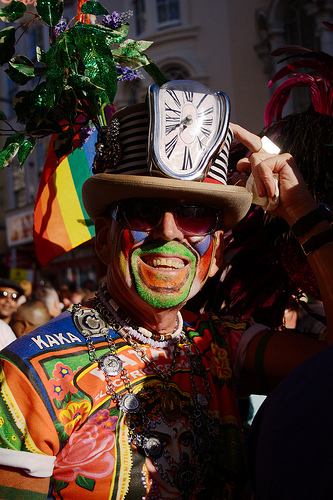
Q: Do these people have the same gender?
A: No, they are both male and female.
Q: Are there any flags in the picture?
A: Yes, there is a flag.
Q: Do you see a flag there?
A: Yes, there is a flag.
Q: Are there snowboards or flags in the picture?
A: Yes, there is a flag.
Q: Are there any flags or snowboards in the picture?
A: Yes, there is a flag.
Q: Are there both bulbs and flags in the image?
A: No, there is a flag but no light bulbs.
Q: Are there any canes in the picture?
A: No, there are no canes.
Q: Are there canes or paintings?
A: No, there are no canes or paintings.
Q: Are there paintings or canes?
A: No, there are no canes or paintings.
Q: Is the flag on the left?
A: Yes, the flag is on the left of the image.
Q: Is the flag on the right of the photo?
A: No, the flag is on the left of the image.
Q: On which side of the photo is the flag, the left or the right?
A: The flag is on the left of the image.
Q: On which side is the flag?
A: The flag is on the left of the image.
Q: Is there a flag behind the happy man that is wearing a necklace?
A: Yes, there is a flag behind the man.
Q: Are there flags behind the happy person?
A: Yes, there is a flag behind the man.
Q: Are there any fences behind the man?
A: No, there is a flag behind the man.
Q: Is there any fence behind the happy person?
A: No, there is a flag behind the man.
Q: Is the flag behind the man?
A: Yes, the flag is behind the man.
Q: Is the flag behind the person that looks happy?
A: Yes, the flag is behind the man.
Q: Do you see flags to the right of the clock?
A: No, the flag is to the left of the clock.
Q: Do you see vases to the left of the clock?
A: No, there is a flag to the left of the clock.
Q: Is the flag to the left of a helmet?
A: No, the flag is to the left of the clock.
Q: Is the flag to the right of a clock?
A: No, the flag is to the left of a clock.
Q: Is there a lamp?
A: No, there are no lamps.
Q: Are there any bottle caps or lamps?
A: No, there are no lamps or bottle caps.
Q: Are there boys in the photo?
A: No, there are no boys.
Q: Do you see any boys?
A: No, there are no boys.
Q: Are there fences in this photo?
A: No, there are no fences.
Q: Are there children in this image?
A: No, there are no children.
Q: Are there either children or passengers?
A: No, there are no children or passengers.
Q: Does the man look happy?
A: Yes, the man is happy.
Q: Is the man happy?
A: Yes, the man is happy.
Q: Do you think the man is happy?
A: Yes, the man is happy.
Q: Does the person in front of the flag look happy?
A: Yes, the man is happy.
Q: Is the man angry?
A: No, the man is happy.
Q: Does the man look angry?
A: No, the man is happy.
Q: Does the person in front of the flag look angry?
A: No, the man is happy.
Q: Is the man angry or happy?
A: The man is happy.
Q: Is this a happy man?
A: Yes, this is a happy man.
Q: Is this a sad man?
A: No, this is a happy man.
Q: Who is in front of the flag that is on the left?
A: The man is in front of the flag.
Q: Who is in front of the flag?
A: The man is in front of the flag.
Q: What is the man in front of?
A: The man is in front of the flag.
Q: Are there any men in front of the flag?
A: Yes, there is a man in front of the flag.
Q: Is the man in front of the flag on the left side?
A: Yes, the man is in front of the flag.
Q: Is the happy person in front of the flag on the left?
A: Yes, the man is in front of the flag.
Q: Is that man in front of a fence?
A: No, the man is in front of the flag.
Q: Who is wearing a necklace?
A: The man is wearing a necklace.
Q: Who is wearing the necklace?
A: The man is wearing a necklace.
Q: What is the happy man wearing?
A: The man is wearing a necklace.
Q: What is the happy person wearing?
A: The man is wearing a necklace.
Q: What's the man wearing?
A: The man is wearing a necklace.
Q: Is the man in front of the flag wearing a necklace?
A: Yes, the man is wearing a necklace.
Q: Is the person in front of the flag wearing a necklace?
A: Yes, the man is wearing a necklace.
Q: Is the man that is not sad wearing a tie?
A: No, the man is wearing a necklace.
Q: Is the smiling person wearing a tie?
A: No, the man is wearing a necklace.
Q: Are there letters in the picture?
A: Yes, there are letters.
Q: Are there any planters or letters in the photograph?
A: Yes, there are letters.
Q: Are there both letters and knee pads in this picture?
A: No, there are letters but no knee pads.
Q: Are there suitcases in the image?
A: No, there are no suitcases.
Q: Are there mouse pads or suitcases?
A: No, there are no suitcases or mouse pads.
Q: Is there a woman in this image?
A: Yes, there is a woman.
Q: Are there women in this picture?
A: Yes, there is a woman.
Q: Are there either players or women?
A: Yes, there is a woman.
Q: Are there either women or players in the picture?
A: Yes, there is a woman.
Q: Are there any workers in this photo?
A: No, there are no workers.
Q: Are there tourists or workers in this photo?
A: No, there are no workers or tourists.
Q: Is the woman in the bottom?
A: Yes, the woman is in the bottom of the image.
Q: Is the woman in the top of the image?
A: No, the woman is in the bottom of the image.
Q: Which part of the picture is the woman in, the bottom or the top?
A: The woman is in the bottom of the image.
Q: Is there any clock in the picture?
A: Yes, there is a clock.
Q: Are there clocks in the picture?
A: Yes, there is a clock.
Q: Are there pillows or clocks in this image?
A: Yes, there is a clock.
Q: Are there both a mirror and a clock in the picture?
A: No, there is a clock but no mirrors.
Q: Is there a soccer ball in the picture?
A: No, there are no soccer balls.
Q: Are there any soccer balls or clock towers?
A: No, there are no soccer balls or clock towers.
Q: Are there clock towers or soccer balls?
A: No, there are no soccer balls or clock towers.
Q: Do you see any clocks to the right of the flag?
A: Yes, there is a clock to the right of the flag.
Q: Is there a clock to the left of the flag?
A: No, the clock is to the right of the flag.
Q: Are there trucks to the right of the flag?
A: No, there is a clock to the right of the flag.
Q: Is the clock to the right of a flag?
A: Yes, the clock is to the right of a flag.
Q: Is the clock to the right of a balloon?
A: No, the clock is to the right of a flag.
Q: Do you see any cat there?
A: No, there are no cats.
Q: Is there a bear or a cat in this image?
A: No, there are no cats or bears.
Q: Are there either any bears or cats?
A: No, there are no cats or bears.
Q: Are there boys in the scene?
A: No, there are no boys.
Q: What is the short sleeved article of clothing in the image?
A: The clothing item is a shirt.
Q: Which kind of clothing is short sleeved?
A: The clothing is a shirt.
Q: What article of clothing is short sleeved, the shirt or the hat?
A: The shirt is short sleeved.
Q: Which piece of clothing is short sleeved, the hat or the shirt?
A: The shirt is short sleeved.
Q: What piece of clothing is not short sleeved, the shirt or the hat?
A: The hat is not short sleeved.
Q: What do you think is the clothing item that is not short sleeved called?
A: The clothing item is a hat.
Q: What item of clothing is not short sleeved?
A: The clothing item is a hat.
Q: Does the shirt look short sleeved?
A: Yes, the shirt is short sleeved.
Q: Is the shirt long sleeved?
A: No, the shirt is short sleeved.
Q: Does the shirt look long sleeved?
A: No, the shirt is short sleeved.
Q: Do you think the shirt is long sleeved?
A: No, the shirt is short sleeved.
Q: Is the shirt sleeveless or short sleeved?
A: The shirt is short sleeved.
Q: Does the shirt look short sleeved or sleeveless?
A: The shirt is short sleeved.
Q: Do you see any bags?
A: No, there are no bags.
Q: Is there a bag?
A: No, there are no bags.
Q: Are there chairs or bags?
A: No, there are no bags or chairs.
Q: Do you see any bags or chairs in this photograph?
A: No, there are no bags or chairs.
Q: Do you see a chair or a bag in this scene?
A: No, there are no bags or chairs.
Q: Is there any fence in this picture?
A: No, there are no fences.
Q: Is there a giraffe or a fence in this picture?
A: No, there are no fences or giraffes.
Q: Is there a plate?
A: No, there are no plates.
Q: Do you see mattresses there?
A: No, there are no mattresses.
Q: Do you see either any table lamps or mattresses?
A: No, there are no mattresses or table lamps.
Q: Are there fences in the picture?
A: No, there are no fences.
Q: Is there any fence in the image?
A: No, there are no fences.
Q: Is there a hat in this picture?
A: Yes, there is a hat.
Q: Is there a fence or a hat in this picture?
A: Yes, there is a hat.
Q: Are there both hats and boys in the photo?
A: No, there is a hat but no boys.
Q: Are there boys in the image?
A: No, there are no boys.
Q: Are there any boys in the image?
A: No, there are no boys.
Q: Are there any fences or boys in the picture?
A: No, there are no boys or fences.